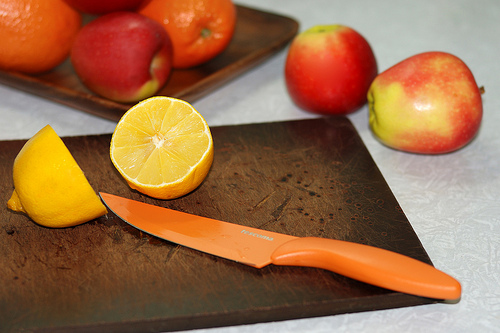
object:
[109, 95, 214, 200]
lemon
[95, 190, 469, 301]
knife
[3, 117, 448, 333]
cutting board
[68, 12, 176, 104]
apple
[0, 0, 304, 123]
cutting board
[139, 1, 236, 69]
orange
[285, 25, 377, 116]
apple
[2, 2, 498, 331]
table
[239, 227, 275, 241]
writting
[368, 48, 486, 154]
apple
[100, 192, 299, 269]
blade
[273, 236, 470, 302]
handle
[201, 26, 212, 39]
end